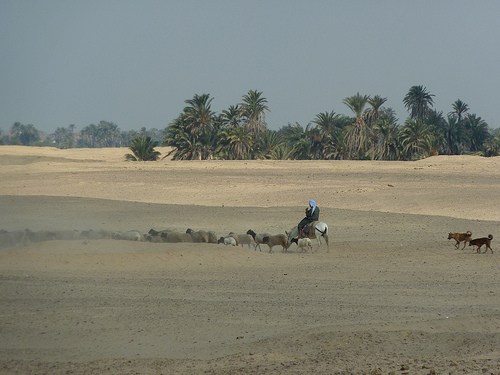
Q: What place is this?
A: It is a desert.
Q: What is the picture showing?
A: It is showing a desert.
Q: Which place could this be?
A: It is a desert.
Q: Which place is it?
A: It is a desert.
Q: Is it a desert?
A: Yes, it is a desert.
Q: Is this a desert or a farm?
A: It is a desert.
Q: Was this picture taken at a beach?
A: No, the picture was taken in a desert.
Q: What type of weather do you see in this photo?
A: It is cloudless.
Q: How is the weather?
A: It is cloudless.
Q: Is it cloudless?
A: Yes, it is cloudless.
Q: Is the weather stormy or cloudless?
A: It is cloudless.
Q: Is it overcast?
A: No, it is cloudless.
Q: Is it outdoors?
A: Yes, it is outdoors.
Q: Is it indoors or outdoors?
A: It is outdoors.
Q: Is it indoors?
A: No, it is outdoors.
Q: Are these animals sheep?
A: No, there are both sheep and donkeys.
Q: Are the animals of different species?
A: Yes, they are sheep and donkeys.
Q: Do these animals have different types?
A: Yes, they are sheep and donkeys.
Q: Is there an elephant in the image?
A: No, there are no elephants.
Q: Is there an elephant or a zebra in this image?
A: No, there are no elephants or zebras.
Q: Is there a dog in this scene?
A: Yes, there is a dog.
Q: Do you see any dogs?
A: Yes, there is a dog.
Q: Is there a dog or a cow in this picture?
A: Yes, there is a dog.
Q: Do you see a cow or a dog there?
A: Yes, there is a dog.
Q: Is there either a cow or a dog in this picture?
A: Yes, there is a dog.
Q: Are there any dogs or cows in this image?
A: Yes, there is a dog.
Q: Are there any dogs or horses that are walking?
A: Yes, the dog is walking.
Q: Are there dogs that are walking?
A: Yes, there is a dog that is walking.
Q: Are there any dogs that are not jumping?
A: Yes, there is a dog that is walking.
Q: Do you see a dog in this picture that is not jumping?
A: Yes, there is a dog that is walking .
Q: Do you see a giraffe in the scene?
A: No, there are no giraffes.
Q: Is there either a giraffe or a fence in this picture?
A: No, there are no giraffes or fences.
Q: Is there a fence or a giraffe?
A: No, there are no giraffes or fences.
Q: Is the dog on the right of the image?
A: Yes, the dog is on the right of the image.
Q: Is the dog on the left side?
A: No, the dog is on the right of the image.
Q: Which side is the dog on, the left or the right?
A: The dog is on the right of the image.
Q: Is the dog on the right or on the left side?
A: The dog is on the right of the image.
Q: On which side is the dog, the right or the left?
A: The dog is on the right of the image.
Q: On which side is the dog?
A: The dog is on the right of the image.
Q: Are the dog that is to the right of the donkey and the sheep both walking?
A: Yes, both the dog and the sheep are walking.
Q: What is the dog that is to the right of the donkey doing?
A: The dog is walking.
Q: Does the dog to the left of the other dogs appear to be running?
A: No, the dog is walking.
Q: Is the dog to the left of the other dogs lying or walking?
A: The dog is walking.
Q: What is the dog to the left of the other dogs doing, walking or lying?
A: The dog is walking.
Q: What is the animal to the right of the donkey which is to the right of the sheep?
A: The animal is a dog.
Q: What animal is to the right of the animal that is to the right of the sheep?
A: The animal is a dog.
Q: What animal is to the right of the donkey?
A: The animal is a dog.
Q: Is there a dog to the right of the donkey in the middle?
A: Yes, there is a dog to the right of the donkey.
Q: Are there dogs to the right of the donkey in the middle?
A: Yes, there is a dog to the right of the donkey.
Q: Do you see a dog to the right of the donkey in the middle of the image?
A: Yes, there is a dog to the right of the donkey.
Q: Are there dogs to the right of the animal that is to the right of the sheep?
A: Yes, there is a dog to the right of the donkey.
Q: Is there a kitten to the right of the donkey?
A: No, there is a dog to the right of the donkey.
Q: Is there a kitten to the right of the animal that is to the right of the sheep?
A: No, there is a dog to the right of the donkey.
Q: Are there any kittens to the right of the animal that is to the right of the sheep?
A: No, there is a dog to the right of the donkey.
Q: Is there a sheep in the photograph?
A: Yes, there is a sheep.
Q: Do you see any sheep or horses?
A: Yes, there is a sheep.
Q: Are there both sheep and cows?
A: No, there is a sheep but no cows.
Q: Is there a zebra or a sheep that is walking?
A: Yes, the sheep is walking.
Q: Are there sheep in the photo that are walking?
A: Yes, there is a sheep that is walking.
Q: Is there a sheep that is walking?
A: Yes, there is a sheep that is walking.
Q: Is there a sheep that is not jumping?
A: Yes, there is a sheep that is walking.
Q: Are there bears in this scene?
A: No, there are no bears.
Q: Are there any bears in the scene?
A: No, there are no bears.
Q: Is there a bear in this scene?
A: No, there are no bears.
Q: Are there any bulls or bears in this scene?
A: No, there are no bears or bulls.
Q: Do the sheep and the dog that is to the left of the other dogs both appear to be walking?
A: Yes, both the sheep and the dog are walking.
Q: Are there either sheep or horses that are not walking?
A: No, there is a sheep but it is walking.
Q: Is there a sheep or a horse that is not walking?
A: No, there is a sheep but it is walking.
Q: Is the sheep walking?
A: Yes, the sheep is walking.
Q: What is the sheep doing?
A: The sheep is walking.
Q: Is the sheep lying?
A: No, the sheep is walking.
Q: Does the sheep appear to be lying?
A: No, the sheep is walking.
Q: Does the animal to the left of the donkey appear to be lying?
A: No, the sheep is walking.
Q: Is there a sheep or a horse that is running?
A: No, there is a sheep but it is walking.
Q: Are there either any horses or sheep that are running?
A: No, there is a sheep but it is walking.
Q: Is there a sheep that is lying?
A: No, there is a sheep but it is walking.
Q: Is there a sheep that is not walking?
A: No, there is a sheep but it is walking.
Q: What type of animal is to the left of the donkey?
A: The animal is a sheep.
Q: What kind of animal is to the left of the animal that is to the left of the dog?
A: The animal is a sheep.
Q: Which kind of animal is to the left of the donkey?
A: The animal is a sheep.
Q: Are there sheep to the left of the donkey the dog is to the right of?
A: Yes, there is a sheep to the left of the donkey.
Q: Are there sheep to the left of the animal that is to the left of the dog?
A: Yes, there is a sheep to the left of the donkey.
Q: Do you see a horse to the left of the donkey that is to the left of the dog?
A: No, there is a sheep to the left of the donkey.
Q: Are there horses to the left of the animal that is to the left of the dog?
A: No, there is a sheep to the left of the donkey.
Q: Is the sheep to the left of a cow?
A: No, the sheep is to the left of a donkey.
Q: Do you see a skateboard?
A: No, there are no skateboards.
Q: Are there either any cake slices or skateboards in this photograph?
A: No, there are no skateboards or cake slices.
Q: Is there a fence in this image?
A: No, there are no fences.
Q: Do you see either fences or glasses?
A: No, there are no fences or glasses.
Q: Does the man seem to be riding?
A: Yes, the man is riding.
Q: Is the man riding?
A: Yes, the man is riding.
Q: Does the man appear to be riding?
A: Yes, the man is riding.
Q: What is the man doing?
A: The man is riding.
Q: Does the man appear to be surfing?
A: No, the man is riding.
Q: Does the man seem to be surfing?
A: No, the man is riding.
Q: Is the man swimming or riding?
A: The man is riding.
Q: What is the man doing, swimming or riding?
A: The man is riding.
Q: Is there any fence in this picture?
A: No, there are no fences.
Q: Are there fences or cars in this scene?
A: No, there are no fences or cars.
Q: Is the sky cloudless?
A: Yes, the sky is cloudless.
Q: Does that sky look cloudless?
A: Yes, the sky is cloudless.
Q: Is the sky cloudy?
A: No, the sky is cloudless.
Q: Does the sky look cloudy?
A: No, the sky is cloudless.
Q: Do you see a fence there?
A: No, there are no fences.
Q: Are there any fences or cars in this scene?
A: No, there are no fences or cars.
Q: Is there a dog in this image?
A: Yes, there are dogs.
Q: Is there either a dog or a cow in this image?
A: Yes, there are dogs.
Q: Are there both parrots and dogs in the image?
A: No, there are dogs but no parrots.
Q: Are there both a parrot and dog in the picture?
A: No, there are dogs but no parrots.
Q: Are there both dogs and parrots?
A: No, there are dogs but no parrots.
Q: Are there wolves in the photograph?
A: No, there are no wolves.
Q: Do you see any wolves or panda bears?
A: No, there are no wolves or panda bears.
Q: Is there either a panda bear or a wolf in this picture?
A: No, there are no wolves or panda bears.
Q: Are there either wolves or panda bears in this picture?
A: No, there are no wolves or panda bears.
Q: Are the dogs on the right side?
A: Yes, the dogs are on the right of the image.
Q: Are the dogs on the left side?
A: No, the dogs are on the right of the image.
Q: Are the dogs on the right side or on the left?
A: The dogs are on the right of the image.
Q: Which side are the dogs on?
A: The dogs are on the right of the image.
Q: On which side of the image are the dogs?
A: The dogs are on the right of the image.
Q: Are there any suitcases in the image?
A: No, there are no suitcases.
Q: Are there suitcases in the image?
A: No, there are no suitcases.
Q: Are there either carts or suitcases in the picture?
A: No, there are no suitcases or carts.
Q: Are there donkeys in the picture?
A: Yes, there is a donkey.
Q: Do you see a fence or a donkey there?
A: Yes, there is a donkey.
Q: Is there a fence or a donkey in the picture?
A: Yes, there is a donkey.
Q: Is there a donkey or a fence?
A: Yes, there is a donkey.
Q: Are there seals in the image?
A: No, there are no seals.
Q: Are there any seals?
A: No, there are no seals.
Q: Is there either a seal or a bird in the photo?
A: No, there are no seals or birds.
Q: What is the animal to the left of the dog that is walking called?
A: The animal is a donkey.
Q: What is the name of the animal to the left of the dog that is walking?
A: The animal is a donkey.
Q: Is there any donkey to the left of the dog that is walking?
A: Yes, there is a donkey to the left of the dog.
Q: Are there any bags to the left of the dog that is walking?
A: No, there is a donkey to the left of the dog.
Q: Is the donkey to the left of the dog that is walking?
A: Yes, the donkey is to the left of the dog.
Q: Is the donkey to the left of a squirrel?
A: No, the donkey is to the left of the dog.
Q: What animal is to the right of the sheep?
A: The animal is a donkey.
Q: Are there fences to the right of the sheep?
A: No, there is a donkey to the right of the sheep.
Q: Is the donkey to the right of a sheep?
A: Yes, the donkey is to the right of a sheep.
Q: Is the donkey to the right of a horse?
A: No, the donkey is to the right of a sheep.